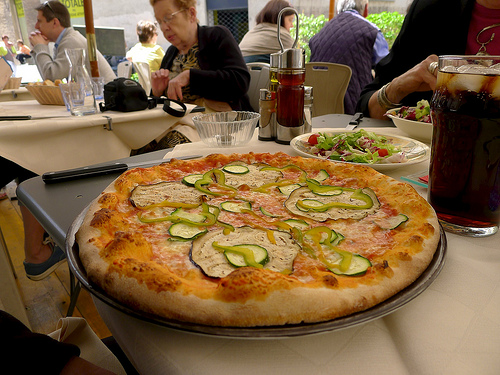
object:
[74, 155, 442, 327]
pizza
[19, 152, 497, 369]
table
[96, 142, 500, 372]
tablecloth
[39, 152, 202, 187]
knife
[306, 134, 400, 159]
salad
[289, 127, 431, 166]
plate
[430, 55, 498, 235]
soda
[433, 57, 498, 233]
glass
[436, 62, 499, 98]
cubes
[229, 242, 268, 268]
cucumber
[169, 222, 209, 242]
cucumber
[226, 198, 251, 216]
cucumber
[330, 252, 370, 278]
cucumber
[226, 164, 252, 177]
cucumber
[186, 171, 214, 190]
cucumber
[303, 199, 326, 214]
cucumber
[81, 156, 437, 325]
crust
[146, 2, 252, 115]
woman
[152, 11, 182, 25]
glasses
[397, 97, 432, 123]
salad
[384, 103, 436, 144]
bowl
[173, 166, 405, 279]
cucumbers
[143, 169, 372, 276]
peppers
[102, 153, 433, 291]
cheese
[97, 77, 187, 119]
bag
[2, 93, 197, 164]
table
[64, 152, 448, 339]
plate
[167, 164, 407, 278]
vegetables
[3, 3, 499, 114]
background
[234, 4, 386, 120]
people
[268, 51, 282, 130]
oil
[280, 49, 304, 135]
vinager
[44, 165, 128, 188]
handle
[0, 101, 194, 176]
cloth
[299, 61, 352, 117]
chair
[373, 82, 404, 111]
bracelets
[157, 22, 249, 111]
sweater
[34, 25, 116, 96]
shirt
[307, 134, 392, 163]
tomatoes